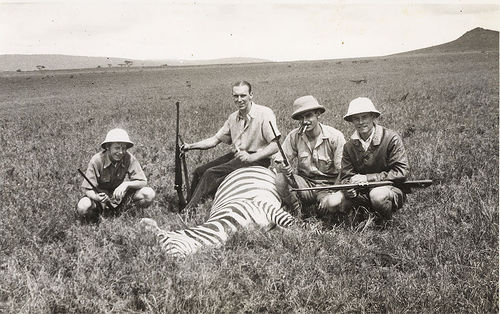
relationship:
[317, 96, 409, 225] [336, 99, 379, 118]
man wearing hat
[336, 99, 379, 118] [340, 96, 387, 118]
hat in head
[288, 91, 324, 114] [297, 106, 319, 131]
hat in man's head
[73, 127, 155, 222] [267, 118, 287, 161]
man posing with gun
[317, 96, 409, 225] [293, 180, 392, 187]
man posing with gun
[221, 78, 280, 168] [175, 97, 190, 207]
man posing with gun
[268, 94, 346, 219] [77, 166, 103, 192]
man posing with gun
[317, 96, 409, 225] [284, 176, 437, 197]
man posing with gun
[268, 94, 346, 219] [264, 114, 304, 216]
man posing with gun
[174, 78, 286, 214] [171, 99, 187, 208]
man posing with gun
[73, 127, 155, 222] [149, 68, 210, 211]
man holding gun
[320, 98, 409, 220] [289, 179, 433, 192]
man holding gun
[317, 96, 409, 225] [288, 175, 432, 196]
man holding gun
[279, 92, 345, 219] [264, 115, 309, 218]
man holding gun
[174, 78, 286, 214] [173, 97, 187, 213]
man holding gun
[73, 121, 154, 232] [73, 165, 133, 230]
man holding gun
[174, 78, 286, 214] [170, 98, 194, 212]
man holding rifle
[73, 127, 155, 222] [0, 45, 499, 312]
man standing in field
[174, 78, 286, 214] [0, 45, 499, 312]
man standing in field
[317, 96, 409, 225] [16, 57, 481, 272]
man standing in field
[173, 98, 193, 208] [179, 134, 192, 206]
rifle held by sling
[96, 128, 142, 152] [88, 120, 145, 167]
hat on head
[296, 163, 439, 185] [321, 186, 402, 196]
gun across lap